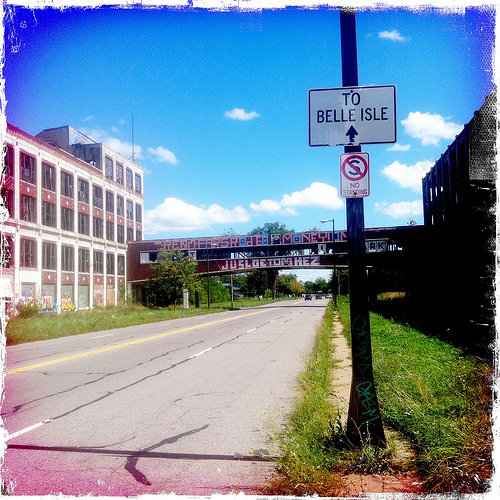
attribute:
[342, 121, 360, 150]
arrow — black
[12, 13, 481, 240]
sky — blue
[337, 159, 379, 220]
sign — red, white